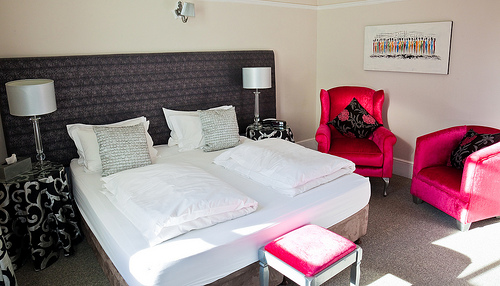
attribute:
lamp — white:
[239, 68, 275, 88]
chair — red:
[316, 88, 394, 176]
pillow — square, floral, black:
[337, 103, 373, 134]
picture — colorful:
[364, 27, 450, 71]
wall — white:
[317, 8, 499, 172]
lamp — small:
[9, 81, 58, 110]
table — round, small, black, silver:
[7, 164, 77, 253]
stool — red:
[258, 224, 373, 280]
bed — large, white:
[76, 142, 361, 266]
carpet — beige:
[343, 193, 492, 286]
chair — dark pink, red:
[414, 129, 499, 219]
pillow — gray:
[92, 124, 152, 169]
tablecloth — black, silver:
[247, 125, 299, 140]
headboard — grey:
[4, 51, 277, 150]